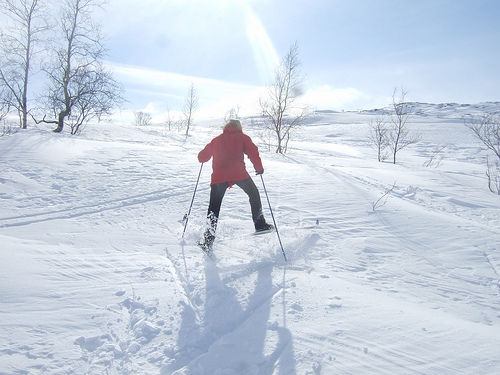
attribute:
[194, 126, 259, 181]
jacket — red 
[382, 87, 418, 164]
tree — bare 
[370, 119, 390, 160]
tree — bare 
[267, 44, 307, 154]
tree — bare 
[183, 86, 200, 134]
tree — bare 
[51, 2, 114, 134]
tree — bare 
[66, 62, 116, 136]
tree — bare 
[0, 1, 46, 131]
tree — bare 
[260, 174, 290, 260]
pole — long 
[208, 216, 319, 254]
ski — long 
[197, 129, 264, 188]
jacket — red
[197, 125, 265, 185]
jacket — red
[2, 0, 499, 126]
clouds — white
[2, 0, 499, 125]
sky — light blue, blue, white, clear, bright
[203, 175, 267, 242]
pants — black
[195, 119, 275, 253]
person — skiing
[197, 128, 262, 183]
coat — red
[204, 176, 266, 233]
pants — black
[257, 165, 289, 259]
pole — ski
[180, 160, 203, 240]
pole — ski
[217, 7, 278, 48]
clouds — white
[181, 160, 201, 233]
ski pole — black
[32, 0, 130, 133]
tree — tall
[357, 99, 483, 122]
mountain — small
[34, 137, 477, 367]
ground — snow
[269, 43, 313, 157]
trees — no leafs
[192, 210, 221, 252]
snow — leg , person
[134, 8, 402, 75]
sky — blue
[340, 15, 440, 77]
clouds — few white 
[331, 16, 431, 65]
sky — blue 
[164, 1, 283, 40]
clouds — few white 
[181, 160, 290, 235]
ski pole — black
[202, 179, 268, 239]
pants — black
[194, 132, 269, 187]
person — red jacket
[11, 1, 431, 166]
trees —  barren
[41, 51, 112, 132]
trees — bare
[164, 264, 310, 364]
snow — shadow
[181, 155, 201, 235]
pole — long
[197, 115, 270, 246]
man — skiing